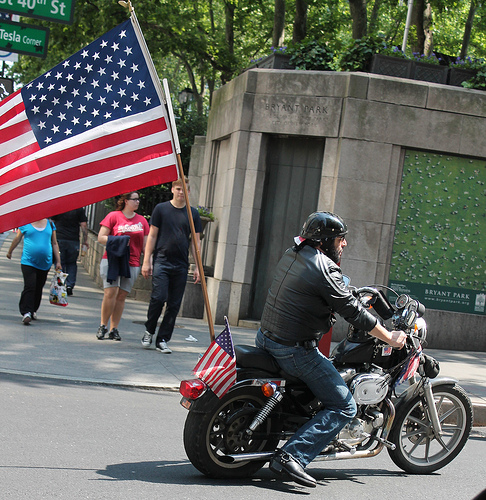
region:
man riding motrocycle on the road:
[170, 207, 478, 486]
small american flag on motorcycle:
[194, 315, 238, 397]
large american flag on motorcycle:
[0, 69, 236, 349]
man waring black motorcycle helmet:
[241, 212, 429, 382]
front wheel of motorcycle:
[377, 369, 477, 473]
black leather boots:
[263, 432, 327, 490]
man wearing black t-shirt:
[130, 173, 213, 355]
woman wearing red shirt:
[77, 189, 156, 347]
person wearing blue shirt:
[7, 208, 72, 335]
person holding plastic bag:
[2, 209, 79, 333]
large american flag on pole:
[6, 1, 178, 204]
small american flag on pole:
[190, 315, 242, 395]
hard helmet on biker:
[300, 211, 344, 251]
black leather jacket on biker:
[257, 243, 375, 352]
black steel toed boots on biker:
[267, 448, 319, 488]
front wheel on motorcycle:
[387, 376, 473, 478]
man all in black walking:
[148, 171, 201, 353]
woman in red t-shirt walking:
[95, 188, 144, 337]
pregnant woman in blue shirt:
[11, 219, 64, 334]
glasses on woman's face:
[126, 193, 143, 204]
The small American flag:
[190, 314, 241, 402]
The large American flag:
[0, 3, 181, 237]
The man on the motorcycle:
[251, 184, 409, 494]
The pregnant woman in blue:
[3, 217, 71, 326]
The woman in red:
[92, 190, 160, 345]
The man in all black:
[136, 176, 204, 354]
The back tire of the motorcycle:
[177, 381, 281, 488]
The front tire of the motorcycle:
[376, 374, 475, 476]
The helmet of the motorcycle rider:
[299, 210, 351, 242]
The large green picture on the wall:
[382, 144, 484, 318]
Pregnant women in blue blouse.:
[20, 213, 57, 274]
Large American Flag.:
[3, 38, 194, 186]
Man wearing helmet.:
[298, 211, 358, 267]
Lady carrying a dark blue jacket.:
[94, 196, 140, 341]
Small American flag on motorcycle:
[189, 320, 268, 426]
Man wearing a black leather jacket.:
[250, 239, 406, 354]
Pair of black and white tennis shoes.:
[139, 329, 176, 357]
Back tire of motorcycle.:
[179, 376, 297, 482]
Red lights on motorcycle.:
[156, 375, 283, 399]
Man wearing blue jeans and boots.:
[259, 354, 352, 487]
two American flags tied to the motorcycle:
[9, 4, 315, 420]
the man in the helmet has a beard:
[289, 208, 350, 263]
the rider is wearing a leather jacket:
[244, 243, 375, 344]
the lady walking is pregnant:
[5, 213, 65, 322]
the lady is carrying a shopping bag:
[46, 254, 70, 307]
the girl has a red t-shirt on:
[100, 195, 147, 272]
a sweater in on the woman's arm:
[97, 222, 134, 290]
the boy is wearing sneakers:
[137, 329, 171, 356]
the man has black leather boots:
[265, 441, 331, 488]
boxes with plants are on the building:
[223, 38, 484, 96]